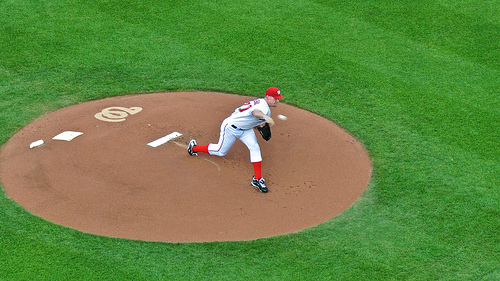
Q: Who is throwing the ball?
A: The pitcher.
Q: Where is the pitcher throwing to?
A: Home plate.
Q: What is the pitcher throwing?
A: A baseball.